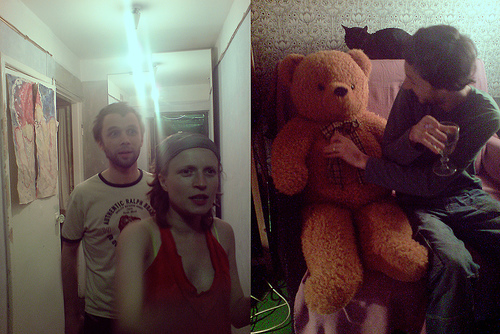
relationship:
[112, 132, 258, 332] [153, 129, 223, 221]
lady has head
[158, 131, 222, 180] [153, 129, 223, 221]
bandana on head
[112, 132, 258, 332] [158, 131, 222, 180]
lady wearing bandana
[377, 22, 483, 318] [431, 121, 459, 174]
man holding a glass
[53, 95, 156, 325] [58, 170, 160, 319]
man wearing a shirt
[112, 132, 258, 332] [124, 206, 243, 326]
lady wearing shirt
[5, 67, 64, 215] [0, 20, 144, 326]
painting hanging on wall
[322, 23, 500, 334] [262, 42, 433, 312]
man sitting next to teddy bear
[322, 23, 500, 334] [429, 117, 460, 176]
man holding cup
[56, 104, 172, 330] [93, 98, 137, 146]
man with hair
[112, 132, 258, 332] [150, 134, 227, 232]
lady with hair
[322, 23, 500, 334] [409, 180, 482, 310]
man wearing pants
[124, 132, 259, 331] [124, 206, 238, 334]
lady has shirt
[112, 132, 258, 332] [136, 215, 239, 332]
lady in shirt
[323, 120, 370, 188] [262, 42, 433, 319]
bowtie on a teddy bear